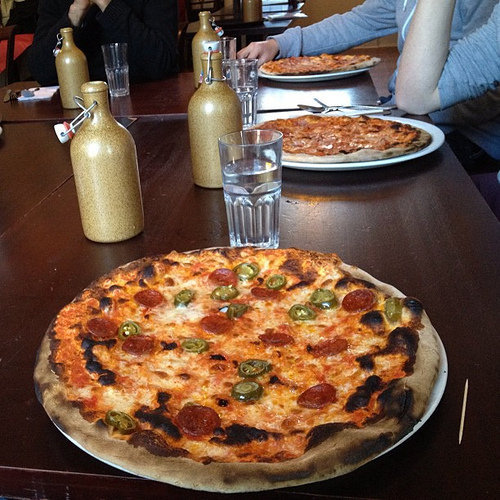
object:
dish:
[30, 243, 449, 495]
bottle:
[186, 47, 244, 190]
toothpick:
[456, 378, 470, 444]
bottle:
[52, 27, 90, 109]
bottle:
[191, 11, 224, 89]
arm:
[391, 0, 498, 117]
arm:
[270, 1, 402, 53]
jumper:
[267, 0, 499, 161]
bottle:
[68, 78, 146, 242]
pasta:
[41, 234, 485, 498]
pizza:
[261, 54, 386, 77]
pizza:
[246, 112, 434, 164]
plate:
[252, 52, 375, 84]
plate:
[240, 107, 446, 174]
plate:
[29, 243, 453, 498]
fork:
[314, 98, 379, 108]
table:
[1, 57, 498, 497]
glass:
[217, 126, 284, 250]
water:
[224, 171, 276, 241]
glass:
[228, 59, 257, 129]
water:
[241, 90, 254, 124]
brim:
[60, 28, 74, 36]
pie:
[35, 245, 441, 491]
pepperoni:
[297, 378, 338, 410]